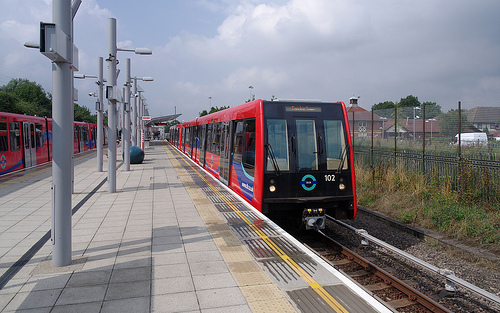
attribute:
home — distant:
[344, 104, 446, 144]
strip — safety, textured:
[165, 136, 350, 311]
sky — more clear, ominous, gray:
[2, 2, 499, 121]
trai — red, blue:
[165, 87, 389, 252]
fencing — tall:
[350, 100, 499, 203]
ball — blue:
[125, 142, 150, 174]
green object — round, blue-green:
[127, 140, 145, 170]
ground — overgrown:
[360, 95, 408, 130]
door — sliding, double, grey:
[20, 117, 37, 169]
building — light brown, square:
[345, 101, 388, 139]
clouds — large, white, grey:
[228, 5, 498, 88]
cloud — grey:
[0, 1, 493, 96]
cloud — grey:
[186, 50, 496, 135]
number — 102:
[323, 173, 338, 182]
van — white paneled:
[450, 125, 489, 148]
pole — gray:
[106, 16, 116, 193]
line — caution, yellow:
[288, 257, 324, 299]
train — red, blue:
[1, 104, 96, 191]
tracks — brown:
[367, 232, 447, 298]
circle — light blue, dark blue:
[299, 174, 318, 189]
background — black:
[265, 171, 350, 201]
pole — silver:
[107, 17, 154, 196]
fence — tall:
[351, 102, 498, 206]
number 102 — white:
[320, 167, 347, 185]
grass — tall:
[350, 132, 496, 263]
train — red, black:
[164, 92, 362, 233]